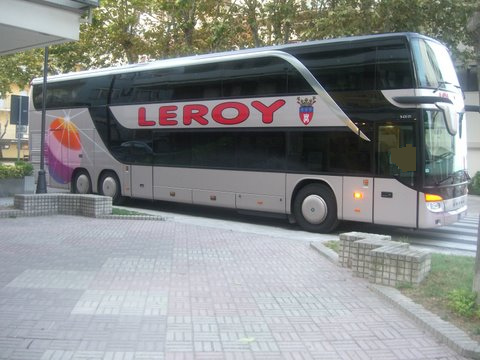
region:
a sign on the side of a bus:
[118, 87, 354, 142]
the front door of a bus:
[370, 115, 430, 242]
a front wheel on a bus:
[277, 169, 349, 243]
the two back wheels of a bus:
[66, 160, 121, 205]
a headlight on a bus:
[425, 194, 447, 216]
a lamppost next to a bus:
[35, 49, 53, 201]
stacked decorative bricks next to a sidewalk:
[338, 224, 433, 296]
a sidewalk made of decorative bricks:
[96, 253, 306, 342]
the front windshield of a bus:
[421, 102, 469, 177]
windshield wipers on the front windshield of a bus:
[430, 73, 462, 101]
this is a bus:
[32, 24, 470, 252]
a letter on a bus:
[128, 90, 154, 142]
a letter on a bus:
[153, 93, 182, 136]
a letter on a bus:
[180, 95, 212, 142]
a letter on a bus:
[207, 99, 249, 138]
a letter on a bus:
[248, 87, 296, 143]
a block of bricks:
[371, 240, 426, 288]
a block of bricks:
[344, 227, 383, 285]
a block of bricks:
[333, 223, 379, 255]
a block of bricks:
[76, 186, 117, 222]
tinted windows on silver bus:
[141, 58, 278, 99]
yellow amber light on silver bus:
[351, 189, 366, 201]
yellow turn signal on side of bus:
[422, 188, 446, 205]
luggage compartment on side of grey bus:
[232, 189, 285, 209]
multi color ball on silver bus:
[41, 115, 84, 190]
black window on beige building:
[11, 93, 29, 130]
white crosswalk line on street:
[425, 220, 475, 250]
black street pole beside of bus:
[39, 76, 52, 189]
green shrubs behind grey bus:
[2, 161, 29, 179]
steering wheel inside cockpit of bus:
[432, 146, 455, 161]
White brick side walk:
[256, 275, 322, 315]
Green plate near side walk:
[437, 270, 479, 321]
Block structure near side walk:
[332, 218, 445, 302]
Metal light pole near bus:
[30, 37, 57, 205]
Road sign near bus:
[4, 88, 35, 130]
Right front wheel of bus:
[284, 170, 342, 235]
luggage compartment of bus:
[142, 166, 289, 221]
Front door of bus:
[362, 118, 434, 244]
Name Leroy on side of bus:
[127, 96, 291, 131]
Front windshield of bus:
[414, 105, 473, 181]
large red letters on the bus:
[136, 103, 285, 123]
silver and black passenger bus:
[27, 32, 469, 231]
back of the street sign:
[8, 94, 30, 124]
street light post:
[37, 46, 48, 191]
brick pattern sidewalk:
[3, 205, 468, 356]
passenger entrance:
[370, 118, 422, 226]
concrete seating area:
[340, 227, 429, 285]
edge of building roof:
[1, 1, 99, 55]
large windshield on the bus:
[420, 107, 468, 176]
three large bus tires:
[69, 165, 341, 231]